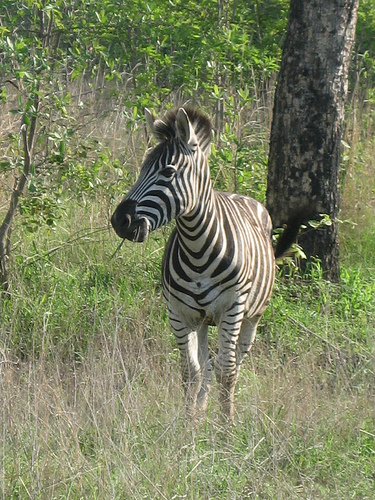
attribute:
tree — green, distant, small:
[0, 34, 64, 273]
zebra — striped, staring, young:
[111, 104, 277, 419]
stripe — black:
[142, 189, 175, 223]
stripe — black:
[155, 178, 181, 215]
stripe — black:
[224, 351, 239, 361]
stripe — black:
[223, 338, 239, 346]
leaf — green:
[56, 104, 68, 117]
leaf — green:
[56, 139, 67, 154]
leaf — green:
[31, 89, 46, 106]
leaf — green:
[14, 69, 26, 85]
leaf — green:
[15, 41, 31, 54]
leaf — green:
[237, 58, 252, 76]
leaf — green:
[145, 98, 161, 110]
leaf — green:
[91, 10, 111, 23]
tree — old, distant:
[265, 0, 360, 279]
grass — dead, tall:
[1, 257, 374, 500]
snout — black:
[110, 200, 134, 238]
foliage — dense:
[0, 1, 373, 97]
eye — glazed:
[159, 164, 177, 180]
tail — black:
[275, 212, 307, 259]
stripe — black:
[165, 314, 183, 325]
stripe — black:
[170, 323, 189, 334]